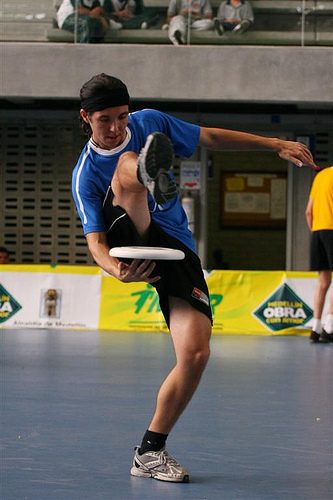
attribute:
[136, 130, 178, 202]
shoe — white, grey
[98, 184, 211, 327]
man's pants — black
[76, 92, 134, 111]
headband — black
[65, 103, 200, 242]
shirt — blue, white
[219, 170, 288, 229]
bulletin board — on the wall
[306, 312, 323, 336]
sock — white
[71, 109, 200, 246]
shirt — white, blue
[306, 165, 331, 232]
t-shirt — bright yellow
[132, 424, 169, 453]
sock — black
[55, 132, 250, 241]
shirt — blue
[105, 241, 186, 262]
frisbee — white, round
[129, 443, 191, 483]
shoe — white, grey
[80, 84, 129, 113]
headband — black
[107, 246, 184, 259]
frisbee — white